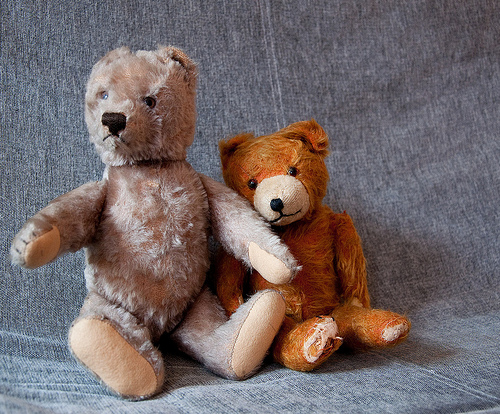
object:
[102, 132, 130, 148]
mouth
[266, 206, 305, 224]
mouth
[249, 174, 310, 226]
muzzle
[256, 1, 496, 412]
seam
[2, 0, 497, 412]
cloth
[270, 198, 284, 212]
nose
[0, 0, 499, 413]
ground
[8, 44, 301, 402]
bear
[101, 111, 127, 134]
nose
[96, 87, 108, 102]
eye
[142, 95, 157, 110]
eye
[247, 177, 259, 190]
eye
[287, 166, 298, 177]
eye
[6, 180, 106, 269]
arm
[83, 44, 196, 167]
head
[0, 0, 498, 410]
couch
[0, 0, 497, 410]
room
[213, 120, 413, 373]
bear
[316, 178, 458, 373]
shadow